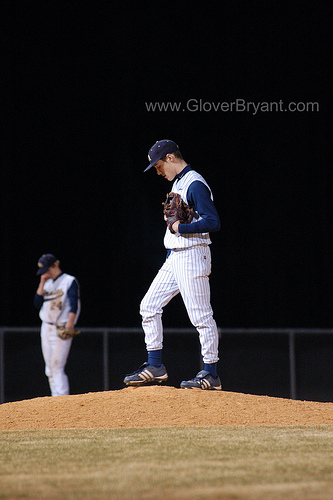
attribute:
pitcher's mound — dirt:
[2, 380, 332, 424]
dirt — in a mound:
[24, 387, 325, 442]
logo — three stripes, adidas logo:
[197, 377, 216, 390]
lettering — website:
[134, 93, 324, 124]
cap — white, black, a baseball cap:
[32, 252, 57, 274]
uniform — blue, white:
[136, 166, 232, 383]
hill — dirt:
[52, 389, 328, 428]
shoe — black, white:
[180, 372, 224, 390]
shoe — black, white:
[124, 363, 169, 389]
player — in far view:
[23, 246, 91, 395]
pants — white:
[138, 247, 230, 357]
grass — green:
[11, 426, 325, 489]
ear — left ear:
[165, 150, 174, 161]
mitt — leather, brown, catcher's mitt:
[162, 192, 194, 232]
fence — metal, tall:
[1, 328, 332, 399]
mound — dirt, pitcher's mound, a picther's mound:
[0, 384, 332, 428]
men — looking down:
[32, 252, 96, 405]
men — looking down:
[122, 132, 235, 392]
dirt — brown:
[2, 387, 329, 423]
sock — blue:
[144, 350, 162, 366]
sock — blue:
[198, 357, 221, 379]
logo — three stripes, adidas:
[137, 370, 155, 383]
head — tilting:
[36, 254, 60, 277]